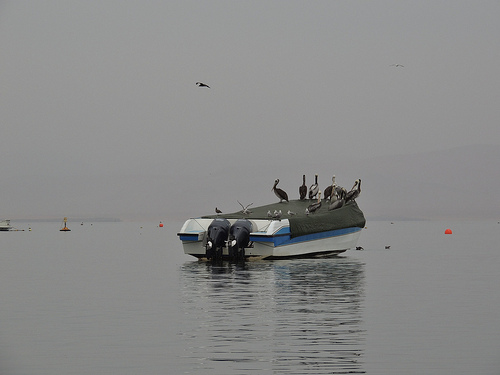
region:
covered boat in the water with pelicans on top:
[179, 171, 366, 277]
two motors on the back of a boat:
[206, 216, 252, 262]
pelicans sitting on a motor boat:
[270, 169, 367, 218]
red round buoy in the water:
[442, 225, 456, 235]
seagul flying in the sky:
[195, 83, 210, 88]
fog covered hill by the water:
[134, 141, 494, 223]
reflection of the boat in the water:
[181, 252, 367, 372]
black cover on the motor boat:
[200, 198, 366, 238]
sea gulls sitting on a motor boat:
[265, 206, 310, 223]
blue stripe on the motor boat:
[177, 219, 364, 247]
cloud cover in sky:
[3, 2, 497, 217]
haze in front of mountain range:
[6, 145, 495, 224]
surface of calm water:
[3, 219, 498, 371]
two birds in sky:
[191, 61, 405, 95]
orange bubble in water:
[443, 226, 455, 234]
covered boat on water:
[178, 193, 365, 264]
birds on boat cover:
[213, 172, 365, 217]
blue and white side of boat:
[179, 215, 367, 258]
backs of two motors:
[204, 216, 253, 263]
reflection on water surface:
[187, 255, 364, 373]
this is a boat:
[178, 175, 380, 265]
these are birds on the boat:
[266, 167, 362, 207]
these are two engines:
[198, 217, 251, 257]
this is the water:
[305, 263, 440, 373]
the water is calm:
[302, 282, 406, 364]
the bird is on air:
[191, 80, 213, 92]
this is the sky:
[274, 21, 460, 121]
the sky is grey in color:
[288, 21, 438, 131]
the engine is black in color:
[206, 216, 229, 262]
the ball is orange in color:
[444, 227, 455, 237]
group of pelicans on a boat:
[266, 156, 360, 220]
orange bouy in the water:
[440, 222, 465, 247]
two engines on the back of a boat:
[207, 204, 249, 263]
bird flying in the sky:
[182, 74, 215, 98]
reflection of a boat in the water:
[214, 245, 367, 372]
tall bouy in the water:
[57, 212, 72, 242]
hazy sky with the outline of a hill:
[122, 106, 457, 185]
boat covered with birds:
[170, 142, 370, 288]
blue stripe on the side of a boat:
[252, 219, 366, 242]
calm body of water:
[98, 272, 313, 345]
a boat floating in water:
[160, 146, 391, 284]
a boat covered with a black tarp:
[220, 195, 366, 254]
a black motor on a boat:
[226, 216, 259, 258]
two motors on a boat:
[198, 209, 254, 259]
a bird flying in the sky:
[189, 63, 231, 103]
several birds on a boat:
[202, 162, 377, 226]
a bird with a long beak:
[268, 174, 289, 204]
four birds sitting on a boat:
[262, 203, 297, 228]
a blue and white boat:
[273, 214, 360, 270]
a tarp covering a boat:
[198, 194, 363, 251]